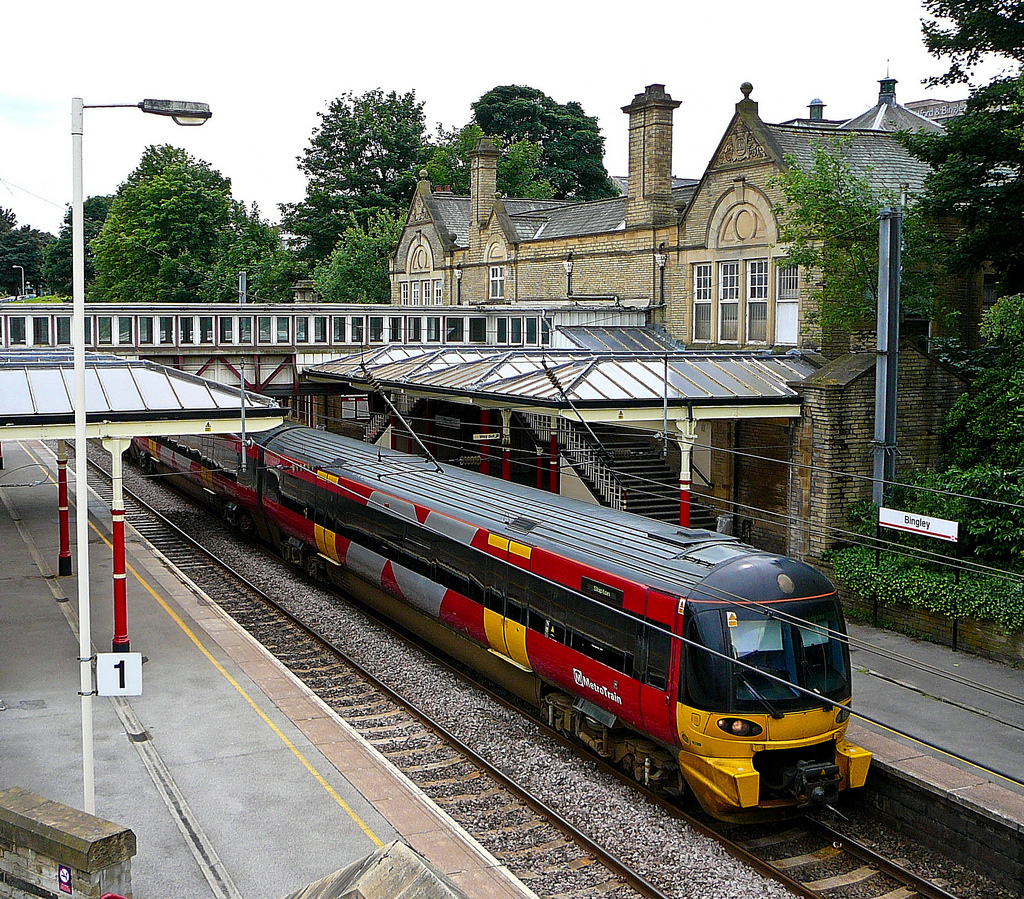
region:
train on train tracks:
[128, 271, 935, 860]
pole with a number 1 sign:
[26, 173, 185, 853]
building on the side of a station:
[310, 73, 999, 586]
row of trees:
[26, 89, 657, 346]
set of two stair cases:
[340, 357, 799, 586]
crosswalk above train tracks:
[1, 252, 811, 762]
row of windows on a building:
[634, 97, 841, 361]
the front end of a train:
[667, 577, 838, 786]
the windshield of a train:
[722, 608, 840, 708]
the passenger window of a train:
[560, 589, 665, 678]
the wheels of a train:
[599, 735, 679, 794]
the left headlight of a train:
[705, 716, 769, 752]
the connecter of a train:
[775, 760, 851, 825]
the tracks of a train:
[788, 834, 886, 895]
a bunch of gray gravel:
[643, 823, 717, 882]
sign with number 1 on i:
[71, 633, 151, 714]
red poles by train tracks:
[52, 430, 150, 655]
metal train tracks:
[52, 433, 650, 895]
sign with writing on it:
[874, 503, 963, 541]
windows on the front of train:
[729, 604, 848, 706]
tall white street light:
[59, 81, 216, 827]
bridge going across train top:
[0, 285, 558, 363]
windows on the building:
[684, 248, 776, 348]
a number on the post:
[89, 650, 138, 690]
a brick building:
[402, 114, 944, 548]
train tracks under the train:
[130, 478, 893, 891]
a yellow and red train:
[122, 361, 868, 814]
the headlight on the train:
[718, 715, 753, 736]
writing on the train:
[563, 661, 620, 697]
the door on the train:
[631, 592, 679, 748]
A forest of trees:
[12, 247, 408, 336]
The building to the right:
[372, 247, 844, 359]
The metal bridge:
[5, 289, 645, 353]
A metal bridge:
[12, 278, 657, 381]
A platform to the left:
[0, 440, 538, 890]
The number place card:
[87, 640, 174, 708]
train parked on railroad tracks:
[109, 387, 890, 834]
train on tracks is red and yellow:
[123, 378, 889, 840]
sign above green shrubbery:
[858, 491, 966, 565]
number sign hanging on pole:
[89, 641, 148, 708]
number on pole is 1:
[89, 644, 144, 708]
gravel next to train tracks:
[60, 434, 794, 897]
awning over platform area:
[3, 344, 291, 696]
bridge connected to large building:
[3, 286, 652, 376]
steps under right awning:
[503, 388, 735, 541]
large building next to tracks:
[376, 59, 1022, 669]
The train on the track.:
[316, 462, 860, 811]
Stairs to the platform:
[585, 429, 740, 531]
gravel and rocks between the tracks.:
[433, 695, 664, 880]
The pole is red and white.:
[98, 429, 150, 630]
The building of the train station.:
[363, 158, 911, 380]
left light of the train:
[683, 715, 789, 742]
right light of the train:
[835, 700, 856, 723]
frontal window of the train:
[689, 617, 836, 691]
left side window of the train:
[498, 580, 636, 669]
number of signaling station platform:
[97, 654, 148, 689]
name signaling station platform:
[876, 511, 946, 538]